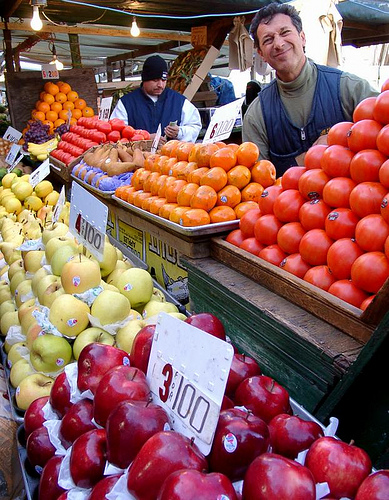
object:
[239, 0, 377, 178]
man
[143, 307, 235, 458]
sign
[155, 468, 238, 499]
apples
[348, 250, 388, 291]
tomatoes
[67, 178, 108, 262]
sign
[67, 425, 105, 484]
apples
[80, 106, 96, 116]
oranges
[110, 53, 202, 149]
man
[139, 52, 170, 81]
hat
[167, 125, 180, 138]
money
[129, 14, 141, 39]
light bulb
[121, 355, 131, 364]
sticker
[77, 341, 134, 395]
apple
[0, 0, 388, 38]
ceiling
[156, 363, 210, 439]
writing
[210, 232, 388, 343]
case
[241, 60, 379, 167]
shirt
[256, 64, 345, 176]
vest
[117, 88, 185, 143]
vest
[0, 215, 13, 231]
pears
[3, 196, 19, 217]
lemons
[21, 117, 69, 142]
grapes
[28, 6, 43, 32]
light bulb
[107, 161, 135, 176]
sweet potatoes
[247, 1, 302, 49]
hair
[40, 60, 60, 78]
sign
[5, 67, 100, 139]
board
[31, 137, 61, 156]
bananas